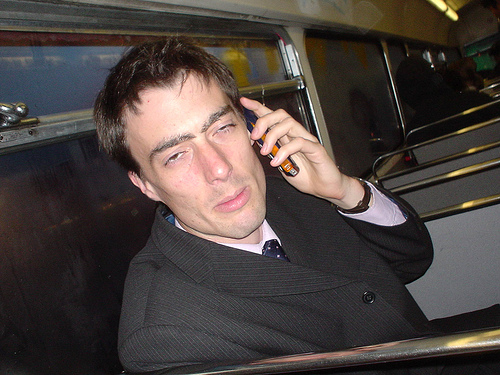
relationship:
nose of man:
[190, 139, 234, 184] [90, 37, 434, 375]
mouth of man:
[211, 184, 251, 214] [90, 37, 434, 375]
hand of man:
[237, 92, 347, 201] [90, 37, 434, 375]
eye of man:
[163, 149, 191, 168] [127, 84, 340, 317]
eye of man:
[212, 120, 234, 137] [118, 87, 323, 291]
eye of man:
[160, 145, 191, 169] [118, 87, 323, 291]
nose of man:
[190, 139, 234, 184] [136, 86, 294, 243]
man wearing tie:
[90, 37, 434, 375] [262, 238, 292, 263]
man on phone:
[73, 36, 440, 323] [238, 100, 309, 195]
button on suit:
[361, 291, 374, 307] [116, 175, 434, 374]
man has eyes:
[90, 37, 434, 375] [166, 115, 246, 167]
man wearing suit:
[90, 37, 434, 375] [116, 175, 434, 374]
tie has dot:
[259, 238, 291, 263] [276, 254, 280, 259]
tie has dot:
[259, 238, 291, 263] [265, 245, 272, 250]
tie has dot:
[259, 238, 291, 263] [275, 244, 278, 249]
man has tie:
[90, 37, 434, 375] [259, 238, 291, 263]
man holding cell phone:
[90, 37, 434, 375] [244, 113, 299, 178]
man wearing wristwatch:
[90, 37, 434, 375] [338, 174, 372, 220]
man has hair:
[90, 37, 434, 375] [91, 33, 251, 175]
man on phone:
[90, 37, 434, 375] [254, 127, 303, 193]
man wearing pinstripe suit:
[90, 37, 434, 375] [116, 176, 435, 375]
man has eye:
[90, 37, 434, 375] [211, 122, 234, 135]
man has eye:
[90, 37, 434, 375] [161, 143, 191, 165]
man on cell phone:
[90, 37, 434, 375] [243, 111, 300, 178]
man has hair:
[90, 37, 434, 375] [91, 49, 239, 76]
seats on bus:
[382, 103, 499, 281] [12, 18, 490, 348]